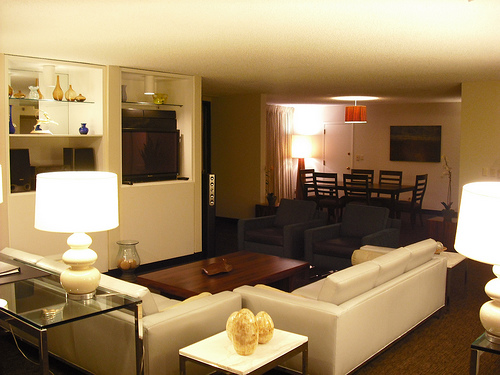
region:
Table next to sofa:
[180, 317, 308, 374]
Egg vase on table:
[233, 309, 259, 355]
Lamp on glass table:
[35, 170, 120, 294]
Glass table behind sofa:
[0, 250, 147, 373]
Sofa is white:
[235, 235, 451, 374]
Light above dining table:
[344, 97, 370, 124]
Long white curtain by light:
[267, 103, 294, 199]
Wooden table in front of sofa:
[135, 242, 315, 297]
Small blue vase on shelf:
[77, 122, 88, 132]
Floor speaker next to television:
[205, 173, 219, 246]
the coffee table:
[122, 242, 313, 291]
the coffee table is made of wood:
[135, 247, 324, 306]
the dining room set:
[297, 164, 432, 219]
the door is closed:
[314, 119, 367, 187]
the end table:
[173, 315, 318, 374]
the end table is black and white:
[168, 316, 305, 371]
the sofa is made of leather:
[250, 232, 450, 372]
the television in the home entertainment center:
[118, 99, 191, 189]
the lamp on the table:
[28, 145, 135, 300]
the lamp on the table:
[453, 164, 498, 335]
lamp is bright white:
[35, 136, 133, 283]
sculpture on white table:
[208, 315, 280, 350]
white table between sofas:
[188, 322, 298, 360]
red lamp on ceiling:
[338, 103, 376, 138]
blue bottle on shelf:
[60, 118, 92, 135]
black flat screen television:
[378, 115, 448, 175]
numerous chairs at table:
[285, 158, 426, 208]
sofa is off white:
[298, 236, 441, 351]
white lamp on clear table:
[35, 161, 130, 289]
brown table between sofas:
[170, 221, 272, 302]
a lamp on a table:
[24, 161, 124, 312]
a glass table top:
[13, 276, 90, 341]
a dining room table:
[296, 163, 430, 207]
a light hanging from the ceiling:
[334, 90, 376, 128]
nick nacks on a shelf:
[26, 74, 88, 104]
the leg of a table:
[127, 306, 158, 373]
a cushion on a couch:
[323, 264, 400, 310]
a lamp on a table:
[451, 173, 496, 350]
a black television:
[117, 119, 189, 191]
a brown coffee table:
[189, 249, 285, 299]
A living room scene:
[0, 25, 481, 366]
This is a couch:
[240, 237, 452, 362]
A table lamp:
[26, 165, 126, 307]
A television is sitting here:
[116, 115, 188, 195]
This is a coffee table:
[130, 240, 305, 295]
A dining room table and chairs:
[295, 152, 430, 202]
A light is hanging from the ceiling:
[335, 87, 372, 132]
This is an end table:
[170, 315, 316, 370]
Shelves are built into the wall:
[1, 51, 107, 136]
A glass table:
[0, 275, 155, 365]